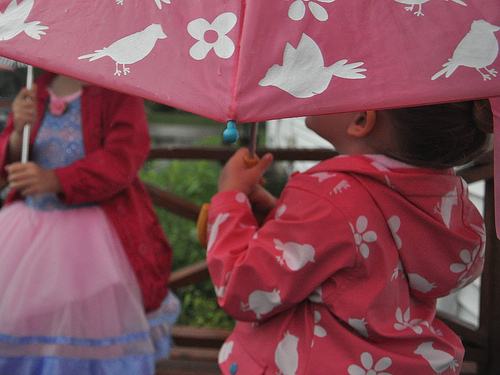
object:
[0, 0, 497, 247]
umbrella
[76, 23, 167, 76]
bird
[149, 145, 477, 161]
railing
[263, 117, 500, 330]
building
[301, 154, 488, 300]
hood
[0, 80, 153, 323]
baby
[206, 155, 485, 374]
jacket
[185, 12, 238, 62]
pattern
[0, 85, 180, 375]
costume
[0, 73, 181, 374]
she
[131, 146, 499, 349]
fence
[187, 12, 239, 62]
flower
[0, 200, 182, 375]
skirt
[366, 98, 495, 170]
hair